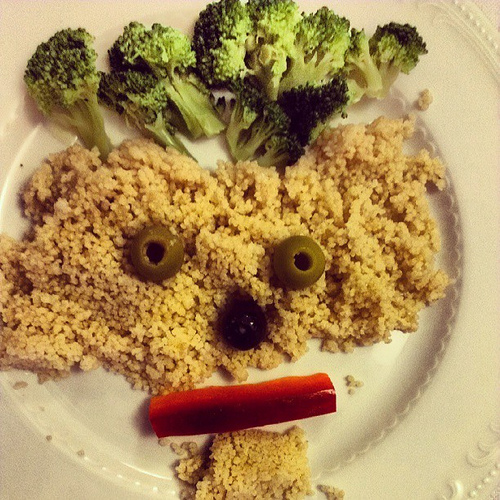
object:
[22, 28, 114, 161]
broccoli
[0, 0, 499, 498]
plate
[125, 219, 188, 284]
olive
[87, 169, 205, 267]
left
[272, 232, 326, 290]
olive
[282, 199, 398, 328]
right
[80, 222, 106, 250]
rice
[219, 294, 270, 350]
olive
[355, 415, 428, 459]
design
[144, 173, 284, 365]
food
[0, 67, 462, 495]
center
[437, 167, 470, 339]
ridges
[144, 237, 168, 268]
holes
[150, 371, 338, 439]
pepper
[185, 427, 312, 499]
grain